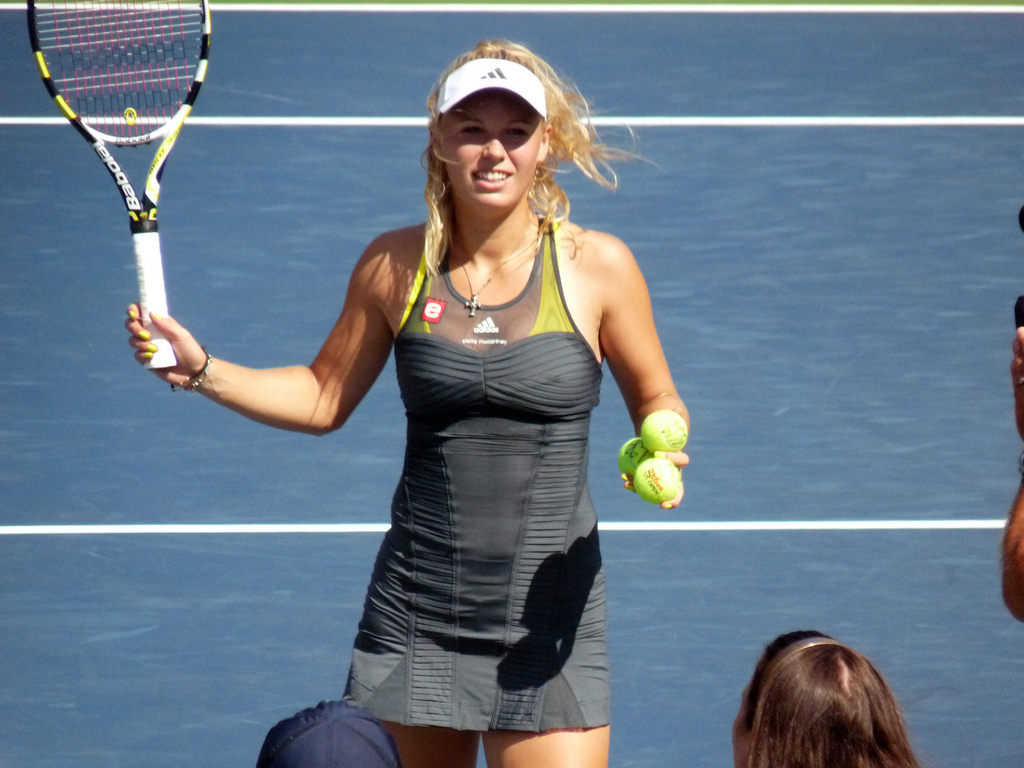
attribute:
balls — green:
[613, 410, 694, 525]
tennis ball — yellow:
[627, 458, 686, 506]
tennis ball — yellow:
[616, 425, 656, 480]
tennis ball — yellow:
[627, 455, 682, 510]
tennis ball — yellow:
[609, 436, 657, 495]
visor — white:
[423, 49, 542, 127]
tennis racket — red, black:
[20, 0, 258, 405]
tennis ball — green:
[627, 466, 679, 506]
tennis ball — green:
[646, 395, 694, 454]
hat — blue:
[255, 689, 389, 763]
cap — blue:
[251, 694, 403, 764]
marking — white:
[2, 517, 992, 539]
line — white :
[0, 518, 1005, 534]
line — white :
[4, 518, 1016, 540]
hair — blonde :
[410, 40, 596, 343]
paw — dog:
[646, 742, 703, 762]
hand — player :
[605, 394, 712, 515]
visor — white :
[430, 61, 569, 128]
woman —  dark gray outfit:
[146, 33, 739, 764]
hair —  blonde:
[391, 26, 649, 305]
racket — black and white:
[19, 5, 221, 369]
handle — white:
[125, 230, 177, 367]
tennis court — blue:
[2, 0, 1022, 765]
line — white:
[0, 513, 1016, 531]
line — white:
[0, 113, 1022, 129]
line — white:
[0, 5, 1022, 12]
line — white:
[0, 515, 1020, 531]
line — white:
[2, 117, 1018, 133]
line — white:
[0, 5, 1024, 23]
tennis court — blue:
[0, 510, 1018, 541]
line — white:
[0, 515, 1018, 537]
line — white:
[2, 106, 1022, 128]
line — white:
[2, 0, 1022, 16]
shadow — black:
[488, 515, 614, 691]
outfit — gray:
[345, 206, 616, 732]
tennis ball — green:
[620, 435, 683, 496]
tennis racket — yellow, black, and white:
[24, 0, 221, 370]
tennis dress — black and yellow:
[343, 212, 616, 731]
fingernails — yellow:
[132, 324, 158, 364]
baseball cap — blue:
[248, 692, 400, 764]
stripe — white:
[0, 513, 1022, 535]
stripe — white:
[0, 108, 1024, 134]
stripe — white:
[0, 0, 1024, 26]